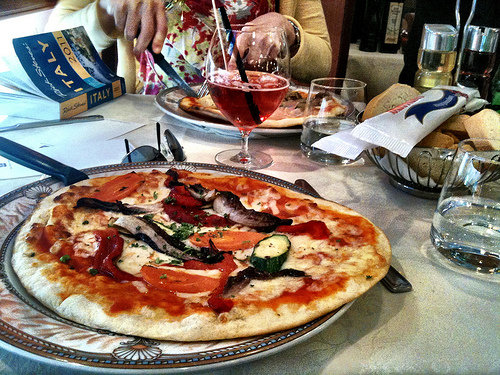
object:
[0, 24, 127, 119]
book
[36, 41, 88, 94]
italy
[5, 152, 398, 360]
pizza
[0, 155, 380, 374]
plate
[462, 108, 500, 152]
bread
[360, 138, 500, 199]
basket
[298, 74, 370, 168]
glass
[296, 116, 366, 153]
water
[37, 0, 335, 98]
woman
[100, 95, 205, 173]
pair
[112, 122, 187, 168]
sunglasses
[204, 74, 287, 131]
juice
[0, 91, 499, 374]
tablecloth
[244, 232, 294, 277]
vegetable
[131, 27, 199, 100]
knife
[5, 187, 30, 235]
designs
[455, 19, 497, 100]
dressing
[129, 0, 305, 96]
blouse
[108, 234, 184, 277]
cheese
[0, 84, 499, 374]
table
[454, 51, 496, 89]
vinegar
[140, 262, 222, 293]
tomatoes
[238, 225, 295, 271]
piece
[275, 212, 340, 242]
squash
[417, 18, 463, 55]
rack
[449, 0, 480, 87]
handled rack